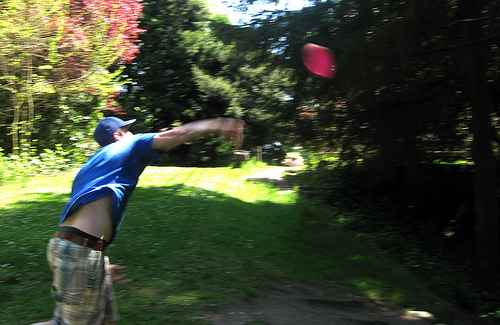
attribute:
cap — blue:
[86, 111, 139, 141]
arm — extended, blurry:
[137, 119, 247, 149]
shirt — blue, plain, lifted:
[69, 132, 165, 231]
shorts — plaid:
[46, 234, 118, 324]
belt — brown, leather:
[44, 226, 109, 254]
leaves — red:
[114, 1, 136, 66]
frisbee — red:
[300, 42, 338, 80]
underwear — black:
[60, 221, 100, 242]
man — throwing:
[46, 108, 255, 318]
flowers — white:
[70, 130, 95, 153]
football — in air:
[293, 33, 366, 81]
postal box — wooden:
[230, 143, 254, 165]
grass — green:
[182, 180, 253, 235]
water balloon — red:
[291, 29, 356, 108]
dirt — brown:
[251, 284, 338, 320]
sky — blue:
[220, 3, 279, 30]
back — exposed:
[62, 205, 117, 234]